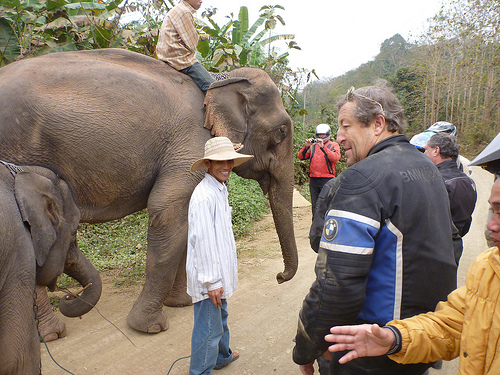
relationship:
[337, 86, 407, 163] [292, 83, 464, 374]
head of man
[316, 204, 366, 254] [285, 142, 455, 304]
part of jacket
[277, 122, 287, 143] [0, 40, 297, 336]
eye of elephant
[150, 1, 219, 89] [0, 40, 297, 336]
man riding on elephant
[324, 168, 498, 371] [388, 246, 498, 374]
man in coat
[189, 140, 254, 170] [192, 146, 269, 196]
hat on head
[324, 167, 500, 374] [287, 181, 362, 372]
man stretching arm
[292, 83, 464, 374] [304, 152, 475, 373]
man wearing jacket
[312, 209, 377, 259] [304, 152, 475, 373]
logo adorning jacket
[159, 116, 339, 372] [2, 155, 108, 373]
man standing in front of elephant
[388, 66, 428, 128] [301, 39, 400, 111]
tree growing in front of hill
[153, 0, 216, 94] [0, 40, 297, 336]
man riding elephant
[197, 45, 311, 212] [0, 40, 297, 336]
head belonging to elephant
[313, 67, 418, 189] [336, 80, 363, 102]
man wearing glasses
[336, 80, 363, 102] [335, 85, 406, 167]
glasses sitting on top of head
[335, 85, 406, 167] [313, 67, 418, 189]
head belonging to man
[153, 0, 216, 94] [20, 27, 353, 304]
man riding elephant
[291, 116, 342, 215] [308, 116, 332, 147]
man wearing helmet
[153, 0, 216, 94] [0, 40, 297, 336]
man sitting on top of elephant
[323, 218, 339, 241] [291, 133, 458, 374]
logo on coat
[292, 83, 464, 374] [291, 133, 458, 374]
man has coat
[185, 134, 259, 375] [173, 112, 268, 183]
man with hat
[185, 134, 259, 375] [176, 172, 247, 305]
man in shirt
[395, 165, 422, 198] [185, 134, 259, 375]
ground under man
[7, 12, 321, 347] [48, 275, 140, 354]
elephant with twig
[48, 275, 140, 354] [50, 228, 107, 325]
twig in trunk